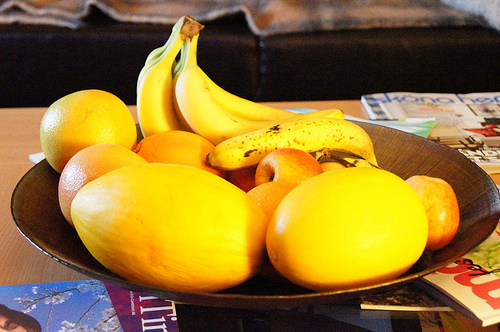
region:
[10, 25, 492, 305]
bowl of some fruit.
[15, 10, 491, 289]
bowl of some delicious fruit.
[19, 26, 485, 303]
bowl of some delightful fruit.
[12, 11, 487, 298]
bowl of some tasty fruit.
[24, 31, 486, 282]
nice bowl of flavorful fruit.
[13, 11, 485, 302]
nice variety of flavorful fruit.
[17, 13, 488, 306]
nice bowl of great fruit.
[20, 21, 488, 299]
great arrangement of fruit for consumption.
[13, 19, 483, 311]
great variety of fruit for consumption.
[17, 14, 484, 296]
nice mixture of delicious fruit.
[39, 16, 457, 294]
the fruit is on a plate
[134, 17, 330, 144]
the bananas are yellow in color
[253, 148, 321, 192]
the apple is red and yellow in color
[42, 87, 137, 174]
the fruit is yellow in color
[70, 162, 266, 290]
the large fruit is yellow in color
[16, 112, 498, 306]
the plate is brown in color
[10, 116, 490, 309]
the bowl is round shaped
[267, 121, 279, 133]
the banana has dark spots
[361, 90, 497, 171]
magazines are on the table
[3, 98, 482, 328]
the table top is light brown in color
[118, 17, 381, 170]
the bananas are yellow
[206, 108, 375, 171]
this banana has many spots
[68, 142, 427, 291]
these fruits appear to be yellow mangos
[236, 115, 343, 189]
the apple has a rosy cheek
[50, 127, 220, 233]
oranges are in the bowl as well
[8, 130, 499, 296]
the bowl is quite large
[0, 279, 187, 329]
the magazine has a picture on the front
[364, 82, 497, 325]
the table has several magazine on it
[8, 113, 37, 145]
the table is made of wood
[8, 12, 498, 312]
this is a nice still life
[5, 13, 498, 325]
Fruits are in a bowl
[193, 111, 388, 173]
Banana is ripe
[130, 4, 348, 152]
Handle of bananas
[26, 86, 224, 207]
Oranges next to bananas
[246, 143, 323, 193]
Apple in the middle of bananas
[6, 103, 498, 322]
Bowl is big and brown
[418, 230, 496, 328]
Magazine under the bowl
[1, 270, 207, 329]
Magazine on the left side of bowl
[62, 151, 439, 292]
Two yellow mangoes on a bowl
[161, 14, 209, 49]
Stem of banana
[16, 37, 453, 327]
fruit in a bowl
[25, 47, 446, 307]
yellow fruit in a bowl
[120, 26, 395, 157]
bananas in a bowl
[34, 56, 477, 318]
fruit in a wooden bowl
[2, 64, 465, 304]
yellow fruit in a wooden bowl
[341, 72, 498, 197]
Magazines on a table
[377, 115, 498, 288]
The edge of a wooden bowl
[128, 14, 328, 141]
A small bunch of bananas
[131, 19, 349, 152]
A small bunch of yellow bananas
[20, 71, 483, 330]
A bowl on a table